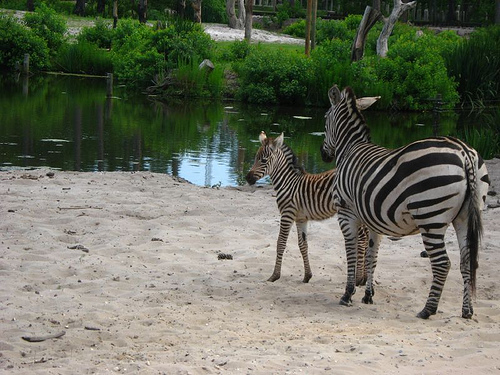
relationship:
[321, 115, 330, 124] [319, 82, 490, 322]
eye on zebra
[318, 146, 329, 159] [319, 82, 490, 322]
nose on zebra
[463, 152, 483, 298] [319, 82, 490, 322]
tail on zebra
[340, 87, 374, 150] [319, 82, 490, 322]
mane on zebra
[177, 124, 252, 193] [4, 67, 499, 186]
reflection on water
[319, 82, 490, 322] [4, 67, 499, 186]
zebra by water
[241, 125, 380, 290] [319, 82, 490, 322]
baby by zebra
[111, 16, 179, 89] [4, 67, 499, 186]
bush behind water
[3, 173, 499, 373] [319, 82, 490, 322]
ground under zebra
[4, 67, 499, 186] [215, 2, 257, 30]
water by tree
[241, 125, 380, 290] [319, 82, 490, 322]
baby with zebra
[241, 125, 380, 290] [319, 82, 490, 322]
baby standing by zebra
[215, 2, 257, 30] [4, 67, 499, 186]
tree reflecting in water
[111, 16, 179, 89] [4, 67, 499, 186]
bush by water